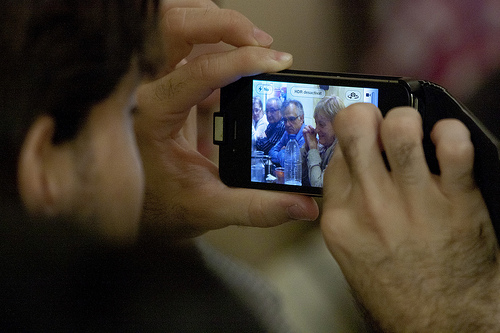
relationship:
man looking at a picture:
[0, 0, 499, 331] [252, 77, 380, 189]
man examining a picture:
[0, 0, 499, 331] [252, 77, 380, 189]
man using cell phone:
[0, 0, 499, 331] [222, 70, 417, 195]